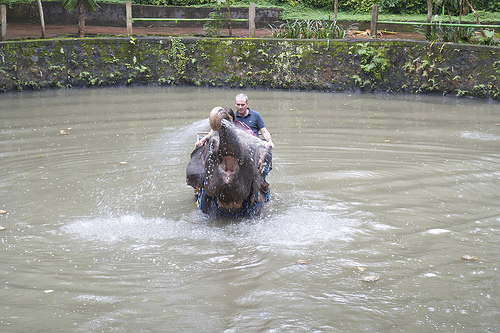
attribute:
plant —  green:
[266, 14, 348, 51]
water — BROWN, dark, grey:
[1, 89, 498, 332]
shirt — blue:
[222, 103, 266, 143]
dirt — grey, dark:
[2, 40, 499, 98]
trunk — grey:
[208, 105, 240, 157]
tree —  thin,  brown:
[363, 0, 385, 41]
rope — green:
[133, 14, 249, 22]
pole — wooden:
[123, 0, 135, 36]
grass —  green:
[309, 3, 489, 44]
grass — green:
[280, 4, 498, 25]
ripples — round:
[8, 113, 497, 199]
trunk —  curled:
[202, 99, 236, 137]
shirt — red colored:
[228, 115, 255, 133]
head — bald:
[231, 92, 255, 117]